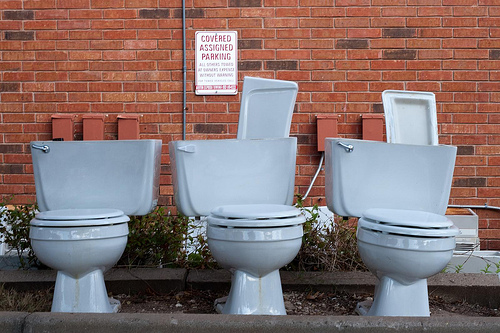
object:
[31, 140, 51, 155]
handle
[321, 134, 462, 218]
tank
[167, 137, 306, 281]
toilet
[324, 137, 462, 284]
toilet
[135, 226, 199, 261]
bushes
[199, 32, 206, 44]
letters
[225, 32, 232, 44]
letters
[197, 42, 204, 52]
letters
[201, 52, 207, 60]
letters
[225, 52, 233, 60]
letters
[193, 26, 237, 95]
sign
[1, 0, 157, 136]
building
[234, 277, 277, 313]
reflection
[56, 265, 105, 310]
reflection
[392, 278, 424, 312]
reflection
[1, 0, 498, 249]
brick building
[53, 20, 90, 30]
brick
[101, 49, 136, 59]
brick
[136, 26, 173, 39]
brick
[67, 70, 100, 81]
brick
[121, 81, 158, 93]
brick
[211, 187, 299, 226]
seat cover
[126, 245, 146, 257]
plants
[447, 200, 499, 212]
pipe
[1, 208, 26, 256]
weed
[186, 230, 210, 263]
weed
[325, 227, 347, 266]
weed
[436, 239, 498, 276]
weed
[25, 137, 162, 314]
toilet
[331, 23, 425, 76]
bricks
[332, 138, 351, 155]
handle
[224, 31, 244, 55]
corner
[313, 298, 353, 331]
ground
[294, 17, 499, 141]
building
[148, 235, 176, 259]
leaves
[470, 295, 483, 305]
ground